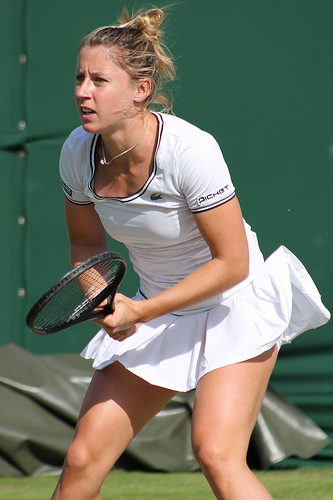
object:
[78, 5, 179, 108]
hair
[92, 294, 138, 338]
hands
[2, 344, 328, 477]
tarp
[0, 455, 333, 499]
court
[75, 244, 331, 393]
skirt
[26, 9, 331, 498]
woman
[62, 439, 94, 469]
knee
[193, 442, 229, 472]
knee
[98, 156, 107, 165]
pendant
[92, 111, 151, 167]
necklace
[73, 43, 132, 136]
face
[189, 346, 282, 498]
leg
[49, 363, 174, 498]
leg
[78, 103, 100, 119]
mouth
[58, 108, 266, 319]
shirt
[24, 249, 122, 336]
racket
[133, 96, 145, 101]
earring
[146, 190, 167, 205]
logo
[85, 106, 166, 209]
line